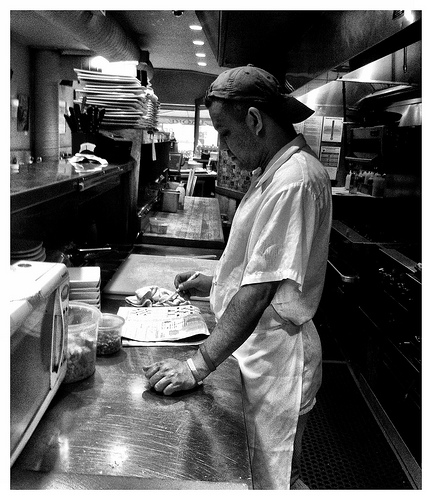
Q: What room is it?
A: It is a kitchen.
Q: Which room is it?
A: It is a kitchen.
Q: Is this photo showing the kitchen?
A: Yes, it is showing the kitchen.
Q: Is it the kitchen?
A: Yes, it is the kitchen.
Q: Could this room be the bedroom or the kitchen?
A: It is the kitchen.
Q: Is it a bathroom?
A: No, it is a kitchen.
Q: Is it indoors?
A: Yes, it is indoors.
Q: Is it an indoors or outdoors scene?
A: It is indoors.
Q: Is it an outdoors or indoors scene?
A: It is indoors.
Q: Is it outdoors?
A: No, it is indoors.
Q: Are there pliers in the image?
A: No, there are no pliers.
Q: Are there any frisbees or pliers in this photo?
A: No, there are no pliers or frisbees.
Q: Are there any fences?
A: No, there are no fences.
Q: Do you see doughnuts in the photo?
A: No, there are no doughnuts.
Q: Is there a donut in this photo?
A: No, there are no donuts.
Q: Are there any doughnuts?
A: No, there are no doughnuts.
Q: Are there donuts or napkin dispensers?
A: No, there are no donuts or napkin dispensers.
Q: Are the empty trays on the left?
A: Yes, the trays are on the left of the image.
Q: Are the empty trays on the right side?
A: No, the trays are on the left of the image.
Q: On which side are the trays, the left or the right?
A: The trays are on the left of the image.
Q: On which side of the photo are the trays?
A: The trays are on the left of the image.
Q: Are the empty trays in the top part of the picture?
A: Yes, the trays are in the top of the image.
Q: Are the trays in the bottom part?
A: No, the trays are in the top of the image.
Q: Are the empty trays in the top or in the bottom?
A: The trays are in the top of the image.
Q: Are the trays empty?
A: Yes, the trays are empty.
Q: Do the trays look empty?
A: Yes, the trays are empty.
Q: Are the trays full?
A: No, the trays are empty.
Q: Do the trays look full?
A: No, the trays are empty.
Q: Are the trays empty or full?
A: The trays are empty.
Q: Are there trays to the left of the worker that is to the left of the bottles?
A: Yes, there are trays to the left of the worker.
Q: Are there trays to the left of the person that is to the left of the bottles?
A: Yes, there are trays to the left of the worker.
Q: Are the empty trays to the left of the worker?
A: Yes, the trays are to the left of the worker.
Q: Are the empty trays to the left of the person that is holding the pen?
A: Yes, the trays are to the left of the worker.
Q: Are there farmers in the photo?
A: No, there are no farmers.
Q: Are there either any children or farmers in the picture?
A: No, there are no farmers or children.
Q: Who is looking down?
A: The worker is looking down.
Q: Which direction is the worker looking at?
A: The worker is looking down.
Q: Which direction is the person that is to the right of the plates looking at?
A: The worker is looking down.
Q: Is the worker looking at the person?
A: Yes, the worker is looking down.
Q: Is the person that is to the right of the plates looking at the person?
A: Yes, the worker is looking down.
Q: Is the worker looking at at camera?
A: No, the worker is looking down.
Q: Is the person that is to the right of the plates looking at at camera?
A: No, the worker is looking down.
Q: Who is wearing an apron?
A: The worker is wearing an apron.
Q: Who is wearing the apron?
A: The worker is wearing an apron.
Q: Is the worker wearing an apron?
A: Yes, the worker is wearing an apron.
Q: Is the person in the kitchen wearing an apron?
A: Yes, the worker is wearing an apron.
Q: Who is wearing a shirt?
A: The worker is wearing a shirt.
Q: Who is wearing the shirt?
A: The worker is wearing a shirt.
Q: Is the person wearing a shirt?
A: Yes, the worker is wearing a shirt.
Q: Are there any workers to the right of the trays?
A: Yes, there is a worker to the right of the trays.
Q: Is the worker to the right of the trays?
A: Yes, the worker is to the right of the trays.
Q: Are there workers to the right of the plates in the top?
A: Yes, there is a worker to the right of the plates.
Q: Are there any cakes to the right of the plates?
A: No, there is a worker to the right of the plates.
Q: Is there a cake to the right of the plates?
A: No, there is a worker to the right of the plates.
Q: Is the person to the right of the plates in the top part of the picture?
A: Yes, the worker is to the right of the plates.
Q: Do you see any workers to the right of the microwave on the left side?
A: Yes, there is a worker to the right of the microwave.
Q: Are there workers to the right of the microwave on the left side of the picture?
A: Yes, there is a worker to the right of the microwave.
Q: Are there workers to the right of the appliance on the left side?
A: Yes, there is a worker to the right of the microwave.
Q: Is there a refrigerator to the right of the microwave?
A: No, there is a worker to the right of the microwave.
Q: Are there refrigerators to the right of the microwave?
A: No, there is a worker to the right of the microwave.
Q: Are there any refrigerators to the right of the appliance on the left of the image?
A: No, there is a worker to the right of the microwave.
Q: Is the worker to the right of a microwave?
A: Yes, the worker is to the right of a microwave.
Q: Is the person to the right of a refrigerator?
A: No, the worker is to the right of a microwave.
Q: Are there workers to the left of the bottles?
A: Yes, there is a worker to the left of the bottles.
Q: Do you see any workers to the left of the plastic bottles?
A: Yes, there is a worker to the left of the bottles.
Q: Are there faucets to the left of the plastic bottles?
A: No, there is a worker to the left of the bottles.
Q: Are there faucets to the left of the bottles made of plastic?
A: No, there is a worker to the left of the bottles.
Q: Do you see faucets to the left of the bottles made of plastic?
A: No, there is a worker to the left of the bottles.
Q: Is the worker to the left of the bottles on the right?
A: Yes, the worker is to the left of the bottles.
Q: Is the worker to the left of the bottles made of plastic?
A: Yes, the worker is to the left of the bottles.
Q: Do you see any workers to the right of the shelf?
A: Yes, there is a worker to the right of the shelf.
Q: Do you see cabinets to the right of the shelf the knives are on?
A: No, there is a worker to the right of the shelf.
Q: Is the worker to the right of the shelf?
A: Yes, the worker is to the right of the shelf.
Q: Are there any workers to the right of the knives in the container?
A: Yes, there is a worker to the right of the knives.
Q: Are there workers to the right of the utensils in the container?
A: Yes, there is a worker to the right of the knives.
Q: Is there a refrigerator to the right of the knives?
A: No, there is a worker to the right of the knives.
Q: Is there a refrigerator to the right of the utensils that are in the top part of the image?
A: No, there is a worker to the right of the knives.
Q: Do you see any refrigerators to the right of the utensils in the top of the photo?
A: No, there is a worker to the right of the knives.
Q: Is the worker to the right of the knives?
A: Yes, the worker is to the right of the knives.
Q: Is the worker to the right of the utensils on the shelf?
A: Yes, the worker is to the right of the knives.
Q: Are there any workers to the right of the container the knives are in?
A: Yes, there is a worker to the right of the container.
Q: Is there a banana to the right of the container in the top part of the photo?
A: No, there is a worker to the right of the container.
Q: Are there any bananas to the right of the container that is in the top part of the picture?
A: No, there is a worker to the right of the container.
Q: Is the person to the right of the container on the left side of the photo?
A: Yes, the worker is to the right of the container.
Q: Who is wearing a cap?
A: The worker is wearing a cap.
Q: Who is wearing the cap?
A: The worker is wearing a cap.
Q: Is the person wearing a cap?
A: Yes, the worker is wearing a cap.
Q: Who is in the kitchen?
A: The worker is in the kitchen.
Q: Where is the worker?
A: The worker is in the kitchen.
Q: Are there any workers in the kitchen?
A: Yes, there is a worker in the kitchen.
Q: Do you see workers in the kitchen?
A: Yes, there is a worker in the kitchen.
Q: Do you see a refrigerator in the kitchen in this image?
A: No, there is a worker in the kitchen.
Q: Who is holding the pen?
A: The worker is holding the pen.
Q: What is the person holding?
A: The worker is holding the pen.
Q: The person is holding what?
A: The worker is holding the pen.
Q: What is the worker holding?
A: The worker is holding the pen.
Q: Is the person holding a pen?
A: Yes, the worker is holding a pen.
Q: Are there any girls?
A: No, there are no girls.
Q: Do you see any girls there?
A: No, there are no girls.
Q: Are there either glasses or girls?
A: No, there are no girls or glasses.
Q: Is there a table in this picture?
A: Yes, there is a table.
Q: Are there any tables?
A: Yes, there is a table.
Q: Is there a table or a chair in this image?
A: Yes, there is a table.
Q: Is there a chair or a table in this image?
A: Yes, there is a table.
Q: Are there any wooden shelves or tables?
A: Yes, there is a wood table.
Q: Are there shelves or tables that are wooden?
A: Yes, the table is wooden.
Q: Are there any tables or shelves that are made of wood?
A: Yes, the table is made of wood.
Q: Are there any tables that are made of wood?
A: Yes, there is a table that is made of wood.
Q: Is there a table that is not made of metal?
A: Yes, there is a table that is made of wood.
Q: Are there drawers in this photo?
A: No, there are no drawers.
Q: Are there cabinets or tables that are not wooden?
A: No, there is a table but it is wooden.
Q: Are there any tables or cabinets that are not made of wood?
A: No, there is a table but it is made of wood.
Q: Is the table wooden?
A: Yes, the table is wooden.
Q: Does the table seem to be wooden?
A: Yes, the table is wooden.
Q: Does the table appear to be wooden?
A: Yes, the table is wooden.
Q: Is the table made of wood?
A: Yes, the table is made of wood.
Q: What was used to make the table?
A: The table is made of wood.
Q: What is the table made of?
A: The table is made of wood.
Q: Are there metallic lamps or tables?
A: No, there is a table but it is wooden.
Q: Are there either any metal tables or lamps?
A: No, there is a table but it is wooden.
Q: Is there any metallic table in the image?
A: No, there is a table but it is wooden.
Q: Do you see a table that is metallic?
A: No, there is a table but it is wooden.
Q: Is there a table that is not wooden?
A: No, there is a table but it is wooden.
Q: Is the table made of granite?
A: No, the table is made of wood.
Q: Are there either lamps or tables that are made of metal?
A: No, there is a table but it is made of wood.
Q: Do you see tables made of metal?
A: No, there is a table but it is made of wood.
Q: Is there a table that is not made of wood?
A: No, there is a table but it is made of wood.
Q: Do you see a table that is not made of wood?
A: No, there is a table but it is made of wood.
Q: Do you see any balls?
A: No, there are no balls.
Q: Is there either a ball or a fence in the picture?
A: No, there are no balls or fences.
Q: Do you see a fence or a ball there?
A: No, there are no balls or fences.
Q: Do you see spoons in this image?
A: No, there are no spoons.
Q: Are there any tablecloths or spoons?
A: No, there are no spoons or tablecloths.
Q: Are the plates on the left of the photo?
A: Yes, the plates are on the left of the image.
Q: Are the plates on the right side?
A: No, the plates are on the left of the image.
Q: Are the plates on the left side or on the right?
A: The plates are on the left of the image.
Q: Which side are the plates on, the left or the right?
A: The plates are on the left of the image.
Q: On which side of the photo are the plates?
A: The plates are on the left of the image.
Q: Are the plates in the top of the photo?
A: Yes, the plates are in the top of the image.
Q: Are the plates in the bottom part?
A: No, the plates are in the top of the image.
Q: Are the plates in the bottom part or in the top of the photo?
A: The plates are in the top of the image.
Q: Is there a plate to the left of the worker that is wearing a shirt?
A: Yes, there are plates to the left of the worker.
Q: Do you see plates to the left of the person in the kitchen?
A: Yes, there are plates to the left of the worker.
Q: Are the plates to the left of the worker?
A: Yes, the plates are to the left of the worker.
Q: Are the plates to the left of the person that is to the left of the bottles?
A: Yes, the plates are to the left of the worker.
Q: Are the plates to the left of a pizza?
A: No, the plates are to the left of the worker.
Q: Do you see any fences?
A: No, there are no fences.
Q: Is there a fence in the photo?
A: No, there are no fences.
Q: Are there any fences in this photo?
A: No, there are no fences.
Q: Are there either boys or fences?
A: No, there are no fences or boys.